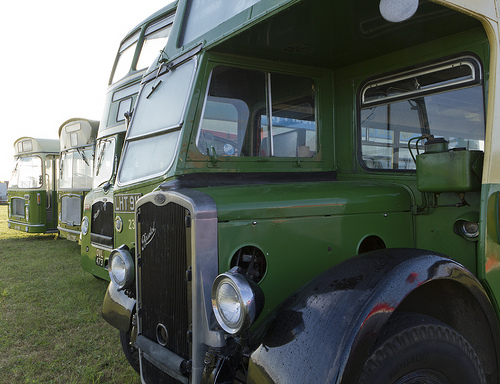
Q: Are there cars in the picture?
A: No, there are no cars.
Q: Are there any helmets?
A: No, there are no helmets.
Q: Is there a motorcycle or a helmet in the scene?
A: No, there are no helmets or motorcycles.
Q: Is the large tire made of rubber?
A: Yes, the tire is made of rubber.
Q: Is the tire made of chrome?
A: No, the tire is made of rubber.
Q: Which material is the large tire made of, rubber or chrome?
A: The tire is made of rubber.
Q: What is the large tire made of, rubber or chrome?
A: The tire is made of rubber.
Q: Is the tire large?
A: Yes, the tire is large.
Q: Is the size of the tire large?
A: Yes, the tire is large.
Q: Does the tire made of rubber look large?
A: Yes, the tire is large.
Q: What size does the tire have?
A: The tire has large size.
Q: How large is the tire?
A: The tire is large.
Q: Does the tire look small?
A: No, the tire is large.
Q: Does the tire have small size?
A: No, the tire is large.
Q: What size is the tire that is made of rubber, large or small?
A: The tire is large.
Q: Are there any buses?
A: Yes, there is a bus.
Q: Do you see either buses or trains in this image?
A: Yes, there is a bus.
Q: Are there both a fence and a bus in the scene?
A: No, there is a bus but no fences.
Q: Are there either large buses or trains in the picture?
A: Yes, there is a large bus.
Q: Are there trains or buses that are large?
A: Yes, the bus is large.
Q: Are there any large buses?
A: Yes, there is a large bus.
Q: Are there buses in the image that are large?
A: Yes, there is a bus that is large.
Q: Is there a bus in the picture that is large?
A: Yes, there is a bus that is large.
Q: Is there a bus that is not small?
A: Yes, there is a large bus.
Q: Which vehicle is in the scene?
A: The vehicle is a bus.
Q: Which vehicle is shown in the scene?
A: The vehicle is a bus.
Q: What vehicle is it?
A: The vehicle is a bus.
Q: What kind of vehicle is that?
A: That is a bus.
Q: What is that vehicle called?
A: That is a bus.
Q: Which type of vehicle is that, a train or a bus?
A: That is a bus.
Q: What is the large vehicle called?
A: The vehicle is a bus.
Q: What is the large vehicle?
A: The vehicle is a bus.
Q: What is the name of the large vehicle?
A: The vehicle is a bus.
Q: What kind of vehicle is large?
A: The vehicle is a bus.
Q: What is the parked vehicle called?
A: The vehicle is a bus.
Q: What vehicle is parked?
A: The vehicle is a bus.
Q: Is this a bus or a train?
A: This is a bus.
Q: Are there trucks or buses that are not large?
A: No, there is a bus but it is large.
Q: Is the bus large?
A: Yes, the bus is large.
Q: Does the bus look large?
A: Yes, the bus is large.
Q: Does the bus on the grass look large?
A: Yes, the bus is large.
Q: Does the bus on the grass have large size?
A: Yes, the bus is large.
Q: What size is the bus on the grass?
A: The bus is large.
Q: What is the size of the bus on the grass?
A: The bus is large.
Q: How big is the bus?
A: The bus is large.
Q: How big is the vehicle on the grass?
A: The bus is large.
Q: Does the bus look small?
A: No, the bus is large.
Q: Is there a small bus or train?
A: No, there is a bus but it is large.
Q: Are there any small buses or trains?
A: No, there is a bus but it is large.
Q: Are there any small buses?
A: No, there is a bus but it is large.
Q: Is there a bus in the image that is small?
A: No, there is a bus but it is large.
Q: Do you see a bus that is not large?
A: No, there is a bus but it is large.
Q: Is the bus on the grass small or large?
A: The bus is large.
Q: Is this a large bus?
A: Yes, this is a large bus.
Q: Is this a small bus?
A: No, this is a large bus.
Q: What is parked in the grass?
A: The bus is parked in the grass.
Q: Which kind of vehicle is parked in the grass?
A: The vehicle is a bus.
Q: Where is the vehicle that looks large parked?
A: The bus is parked in the grass.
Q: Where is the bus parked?
A: The bus is parked in the grass.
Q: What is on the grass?
A: The bus is on the grass.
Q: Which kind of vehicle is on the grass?
A: The vehicle is a bus.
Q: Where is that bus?
A: The bus is on the grass.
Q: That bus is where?
A: The bus is on the grass.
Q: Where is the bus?
A: The bus is on the grass.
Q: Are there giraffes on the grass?
A: No, there is a bus on the grass.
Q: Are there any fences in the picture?
A: No, there are no fences.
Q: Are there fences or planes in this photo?
A: No, there are no fences or planes.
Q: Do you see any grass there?
A: Yes, there is grass.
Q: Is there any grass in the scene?
A: Yes, there is grass.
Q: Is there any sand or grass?
A: Yes, there is grass.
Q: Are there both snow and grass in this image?
A: No, there is grass but no snow.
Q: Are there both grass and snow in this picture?
A: No, there is grass but no snow.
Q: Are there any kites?
A: No, there are no kites.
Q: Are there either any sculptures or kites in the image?
A: No, there are no kites or sculptures.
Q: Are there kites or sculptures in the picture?
A: No, there are no kites or sculptures.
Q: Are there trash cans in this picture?
A: No, there are no trash cans.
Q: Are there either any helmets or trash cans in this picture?
A: No, there are no trash cans or helmets.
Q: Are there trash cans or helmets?
A: No, there are no trash cans or helmets.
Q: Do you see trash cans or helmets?
A: No, there are no trash cans or helmets.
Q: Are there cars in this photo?
A: No, there are no cars.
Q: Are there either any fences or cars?
A: No, there are no cars or fences.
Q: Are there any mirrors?
A: Yes, there is a mirror.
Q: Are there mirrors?
A: Yes, there is a mirror.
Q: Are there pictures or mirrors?
A: Yes, there is a mirror.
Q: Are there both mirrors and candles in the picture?
A: No, there is a mirror but no candles.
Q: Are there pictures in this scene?
A: No, there are no pictures.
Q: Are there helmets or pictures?
A: No, there are no pictures or helmets.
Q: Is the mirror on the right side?
A: Yes, the mirror is on the right of the image.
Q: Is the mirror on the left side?
A: No, the mirror is on the right of the image.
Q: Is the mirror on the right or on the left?
A: The mirror is on the right of the image.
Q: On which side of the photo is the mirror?
A: The mirror is on the right of the image.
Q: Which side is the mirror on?
A: The mirror is on the right of the image.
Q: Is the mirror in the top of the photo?
A: Yes, the mirror is in the top of the image.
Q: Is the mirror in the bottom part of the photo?
A: No, the mirror is in the top of the image.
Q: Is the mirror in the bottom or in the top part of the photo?
A: The mirror is in the top of the image.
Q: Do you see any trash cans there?
A: No, there are no trash cans.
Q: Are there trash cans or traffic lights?
A: No, there are no trash cans or traffic lights.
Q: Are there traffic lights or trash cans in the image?
A: No, there are no trash cans or traffic lights.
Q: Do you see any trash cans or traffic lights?
A: No, there are no trash cans or traffic lights.